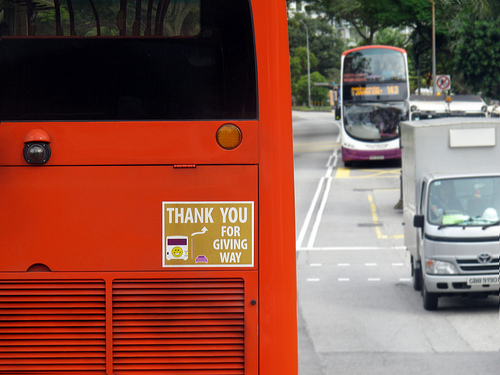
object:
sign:
[162, 201, 254, 268]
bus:
[3, 0, 296, 375]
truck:
[399, 116, 499, 309]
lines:
[307, 177, 332, 247]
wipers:
[439, 216, 479, 229]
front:
[339, 45, 410, 160]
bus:
[337, 45, 407, 169]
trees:
[417, 0, 499, 92]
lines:
[368, 194, 383, 238]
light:
[373, 54, 404, 75]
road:
[294, 111, 500, 374]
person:
[432, 182, 463, 215]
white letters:
[239, 206, 248, 224]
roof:
[343, 45, 406, 55]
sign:
[436, 75, 451, 90]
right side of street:
[374, 101, 500, 375]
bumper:
[342, 147, 401, 160]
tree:
[289, 16, 335, 108]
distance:
[290, 0, 499, 111]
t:
[167, 208, 174, 223]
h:
[175, 208, 184, 224]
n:
[194, 208, 203, 224]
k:
[205, 207, 214, 223]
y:
[220, 207, 230, 223]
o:
[228, 207, 238, 223]